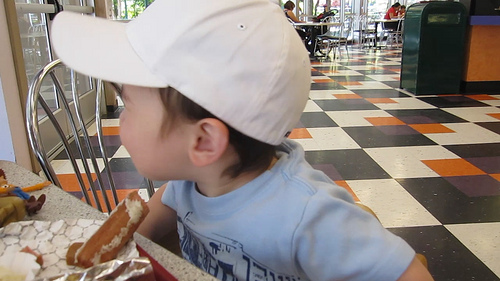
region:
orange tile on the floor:
[420, 155, 488, 177]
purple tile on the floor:
[375, 123, 417, 138]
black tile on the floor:
[340, 122, 437, 151]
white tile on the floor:
[360, 143, 460, 178]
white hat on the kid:
[51, 0, 315, 148]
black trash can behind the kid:
[397, 0, 474, 97]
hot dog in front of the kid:
[71, 190, 151, 267]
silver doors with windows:
[3, 0, 110, 167]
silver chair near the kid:
[22, 55, 155, 214]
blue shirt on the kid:
[158, 138, 417, 279]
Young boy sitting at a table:
[50, 0, 435, 279]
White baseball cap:
[50, 0, 313, 147]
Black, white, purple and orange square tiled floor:
[33, 39, 495, 277]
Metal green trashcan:
[400, 1, 470, 96]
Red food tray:
[0, 189, 180, 279]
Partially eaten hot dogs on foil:
[0, 188, 154, 279]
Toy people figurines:
[1, 165, 51, 222]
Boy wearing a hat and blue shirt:
[48, 0, 430, 280]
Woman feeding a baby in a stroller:
[281, 0, 339, 52]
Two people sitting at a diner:
[379, 1, 407, 46]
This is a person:
[81, 9, 372, 276]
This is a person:
[283, 0, 303, 45]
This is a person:
[379, 0, 399, 42]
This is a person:
[398, 0, 411, 31]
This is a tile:
[323, 138, 390, 185]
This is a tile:
[377, 133, 440, 185]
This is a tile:
[360, 172, 438, 228]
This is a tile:
[419, 171, 480, 230]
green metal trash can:
[398, 1, 469, 96]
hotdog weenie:
[76, 190, 148, 264]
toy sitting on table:
[0, 168, 50, 213]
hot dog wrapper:
[1, 215, 156, 279]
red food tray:
[133, 243, 178, 279]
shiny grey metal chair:
[26, 57, 161, 219]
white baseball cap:
[47, 0, 311, 147]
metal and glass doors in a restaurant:
[3, 0, 108, 166]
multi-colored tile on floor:
[38, 38, 498, 280]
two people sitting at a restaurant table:
[281, 0, 355, 63]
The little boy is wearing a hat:
[50, 4, 315, 197]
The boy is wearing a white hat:
[46, 1, 309, 187]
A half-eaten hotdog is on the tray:
[62, 178, 159, 269]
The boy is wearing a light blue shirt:
[145, 138, 418, 278]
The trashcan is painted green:
[397, 4, 469, 99]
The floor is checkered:
[316, 38, 482, 249]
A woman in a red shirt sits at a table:
[365, 6, 407, 44]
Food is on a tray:
[0, 198, 182, 275]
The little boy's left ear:
[187, 113, 231, 181]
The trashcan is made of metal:
[395, 3, 474, 102]